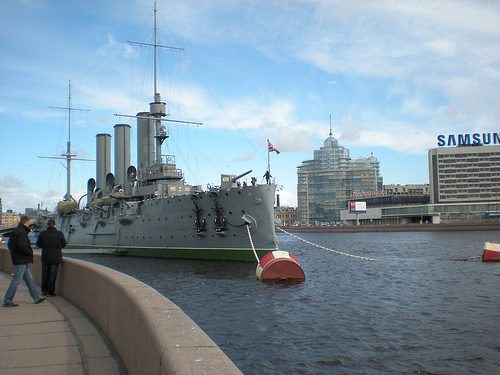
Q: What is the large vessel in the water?
A: A ship.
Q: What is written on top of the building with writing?
A: SAMSUNG.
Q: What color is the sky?
A: Blue.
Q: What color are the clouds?
A: White.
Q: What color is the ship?
A: Gray.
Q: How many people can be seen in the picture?
A: 2.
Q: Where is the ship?
A: In the water.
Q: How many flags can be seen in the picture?
A: 1.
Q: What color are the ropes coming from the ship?
A: White.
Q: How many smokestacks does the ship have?
A: 3.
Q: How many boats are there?
A: 1.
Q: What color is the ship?
A: Gray.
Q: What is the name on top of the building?
A: Samsung.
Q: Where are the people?
A: On the sidewalk.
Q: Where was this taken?
A: Harbor.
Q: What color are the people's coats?
A: Black.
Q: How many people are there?
A: 2.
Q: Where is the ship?
A: In the water.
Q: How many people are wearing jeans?
A: 1.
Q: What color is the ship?
A: Gray.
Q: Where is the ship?
A: In water.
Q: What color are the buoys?
A: Red and white.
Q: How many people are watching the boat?
A: Two.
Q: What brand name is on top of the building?
A: Samsung.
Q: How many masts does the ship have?
A: Two.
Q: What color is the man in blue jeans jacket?
A: Black.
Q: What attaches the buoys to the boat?
A: Chains.